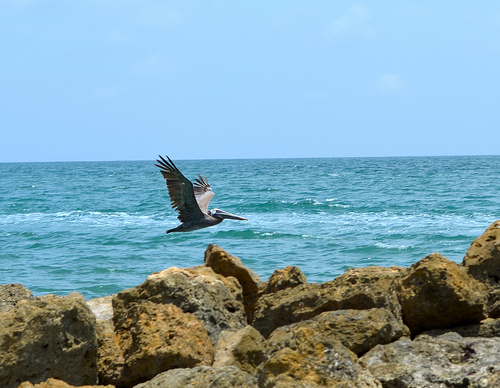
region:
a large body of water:
[3, 155, 498, 299]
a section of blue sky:
[1, 0, 496, 161]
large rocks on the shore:
[0, 220, 497, 385]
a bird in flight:
[152, 155, 247, 230]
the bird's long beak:
[215, 210, 245, 220]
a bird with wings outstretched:
[156, 154, 248, 231]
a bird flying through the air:
[155, 152, 250, 235]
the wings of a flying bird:
[155, 155, 210, 220]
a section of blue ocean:
[0, 157, 498, 299]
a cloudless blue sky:
[0, 0, 496, 163]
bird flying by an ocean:
[139, 144, 253, 245]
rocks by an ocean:
[5, 250, 485, 380]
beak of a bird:
[220, 206, 245, 222]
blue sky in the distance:
[37, 15, 449, 117]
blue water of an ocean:
[250, 162, 475, 239]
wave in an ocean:
[61, 200, 162, 225]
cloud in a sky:
[317, 1, 362, 46]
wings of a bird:
[155, 150, 215, 215]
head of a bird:
[207, 201, 244, 223]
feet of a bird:
[160, 223, 178, 233]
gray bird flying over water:
[148, 149, 233, 240]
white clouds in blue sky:
[16, 3, 110, 65]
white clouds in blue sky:
[11, 55, 95, 106]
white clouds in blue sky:
[25, 85, 99, 145]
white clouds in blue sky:
[112, 12, 192, 60]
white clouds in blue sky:
[125, 52, 192, 120]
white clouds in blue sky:
[209, 11, 281, 83]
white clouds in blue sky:
[233, 62, 288, 107]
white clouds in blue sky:
[331, 21, 425, 68]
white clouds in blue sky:
[333, 82, 454, 132]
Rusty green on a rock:
[263, 349, 307, 376]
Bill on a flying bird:
[218, 212, 248, 222]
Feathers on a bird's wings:
[149, 156, 214, 209]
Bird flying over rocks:
[147, 155, 253, 237]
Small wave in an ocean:
[253, 195, 343, 214]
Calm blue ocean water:
[1, 163, 496, 203]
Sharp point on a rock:
[200, 240, 230, 266]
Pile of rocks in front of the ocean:
[1, 220, 498, 386]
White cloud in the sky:
[323, 6, 378, 36]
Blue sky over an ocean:
[1, 3, 499, 148]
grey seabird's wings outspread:
[153, 147, 218, 218]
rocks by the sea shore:
[1, 236, 478, 385]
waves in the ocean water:
[263, 185, 481, 235]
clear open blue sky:
[5, 14, 497, 157]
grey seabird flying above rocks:
[144, 138, 248, 238]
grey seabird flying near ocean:
[141, 148, 250, 238]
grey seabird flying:
[141, 137, 264, 241]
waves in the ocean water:
[19, 185, 161, 241]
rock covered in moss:
[258, 323, 373, 385]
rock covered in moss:
[386, 250, 481, 323]